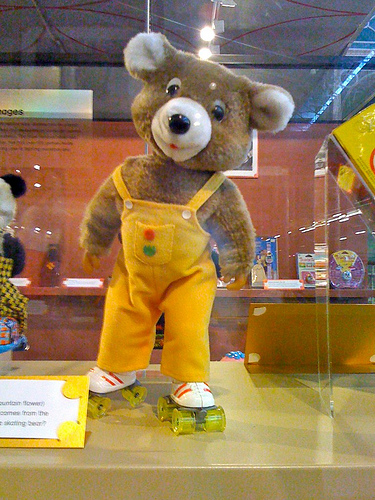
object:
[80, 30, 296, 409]
bear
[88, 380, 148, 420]
skates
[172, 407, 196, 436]
wheel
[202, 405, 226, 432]
wheel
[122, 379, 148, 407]
wheel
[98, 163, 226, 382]
outfit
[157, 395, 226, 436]
skate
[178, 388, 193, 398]
stripe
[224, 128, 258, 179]
picture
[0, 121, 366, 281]
wall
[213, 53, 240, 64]
reflection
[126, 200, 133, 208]
button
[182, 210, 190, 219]
button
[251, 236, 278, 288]
picture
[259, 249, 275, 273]
beast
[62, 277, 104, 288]
sign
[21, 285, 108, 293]
top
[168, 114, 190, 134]
nose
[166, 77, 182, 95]
eye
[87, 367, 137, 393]
shoe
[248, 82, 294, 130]
ear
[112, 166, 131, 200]
strap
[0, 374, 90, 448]
placard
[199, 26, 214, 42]
light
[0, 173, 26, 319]
bear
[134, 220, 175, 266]
pocket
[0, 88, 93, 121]
sign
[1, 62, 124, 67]
bar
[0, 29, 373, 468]
display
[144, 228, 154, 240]
button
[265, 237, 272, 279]
watch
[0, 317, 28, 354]
seat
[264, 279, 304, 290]
sign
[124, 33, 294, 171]
head